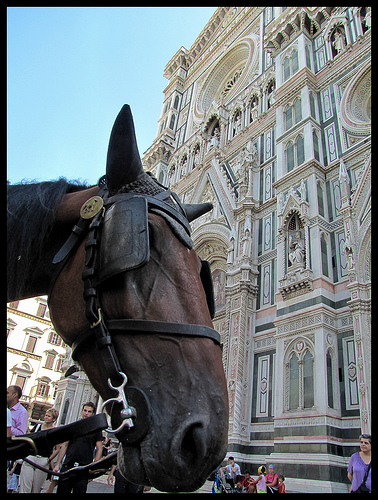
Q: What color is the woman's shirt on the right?
A: Purple.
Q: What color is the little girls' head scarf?
A: Yellow.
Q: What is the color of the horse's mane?
A: Black.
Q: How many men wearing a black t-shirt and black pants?
A: 1.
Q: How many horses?
A: 1.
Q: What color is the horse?
A: Brown.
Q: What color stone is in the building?
A: Pink and gray.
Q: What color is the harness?
A: Black.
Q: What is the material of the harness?
A: Leather.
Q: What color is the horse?
A: Brown.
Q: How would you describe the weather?
A: Sunny, clear skies.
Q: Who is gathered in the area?
A: Tourists.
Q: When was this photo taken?
A: In the morning, the shadows are still long.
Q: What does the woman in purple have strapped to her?
A: Her purse.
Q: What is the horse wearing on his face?
A: His bridle and blinders.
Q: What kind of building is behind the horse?
A: A church.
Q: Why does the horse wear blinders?
A: So he isn't spooked by sudden movement beside him.